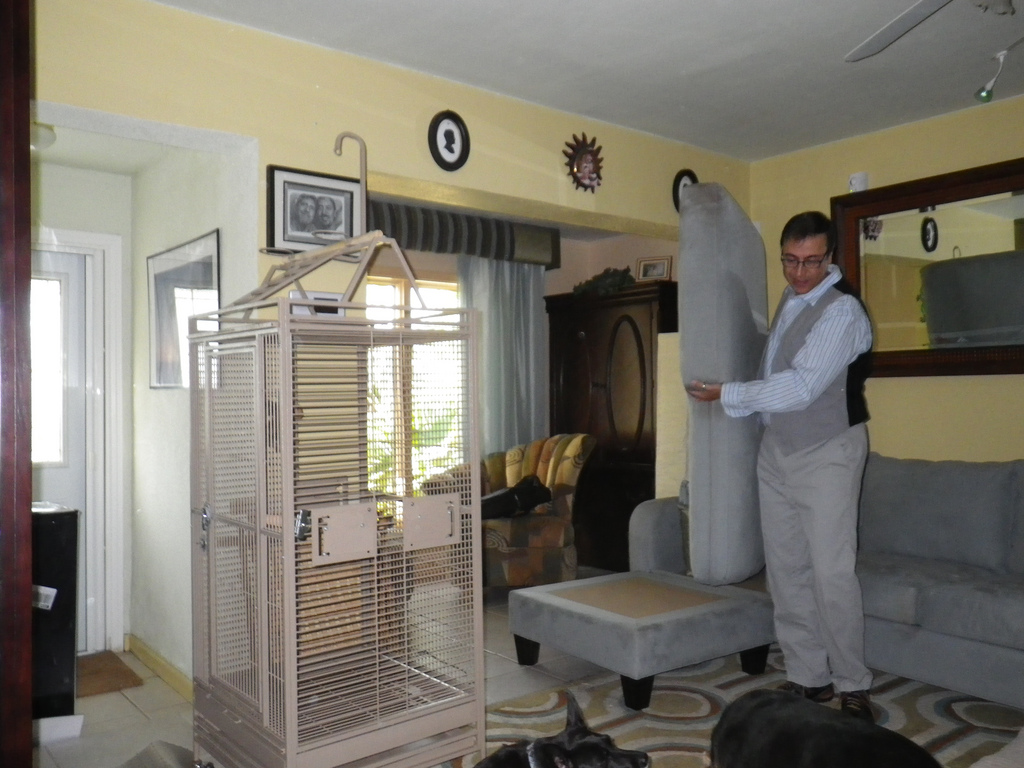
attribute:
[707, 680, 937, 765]
black dog — bigger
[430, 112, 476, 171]
picture — black, oval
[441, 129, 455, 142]
head — silhouette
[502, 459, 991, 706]
grey couch — long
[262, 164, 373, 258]
framed photo — black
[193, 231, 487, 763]
birdcage — light brown, tall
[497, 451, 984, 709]
sofa — light, gray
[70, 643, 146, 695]
mat — door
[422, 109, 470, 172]
picture — round, black, framed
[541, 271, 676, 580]
cabinet — wooden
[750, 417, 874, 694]
pants — gray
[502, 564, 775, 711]
footrest — gray, brown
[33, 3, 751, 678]
wall — matte yellow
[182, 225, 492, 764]
bird cage — tall, cream colored, tan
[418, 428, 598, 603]
chair — multi-color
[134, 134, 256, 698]
wall — white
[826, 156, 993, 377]
mirror — wooden, framed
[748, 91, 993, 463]
wall — yellow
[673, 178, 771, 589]
cushion — sofa